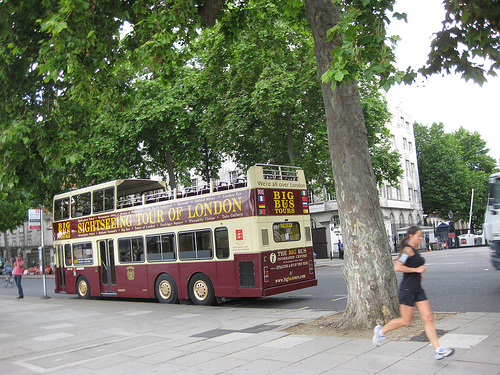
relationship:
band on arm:
[398, 250, 409, 264] [395, 244, 424, 273]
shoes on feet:
[373, 324, 455, 361] [374, 329, 454, 360]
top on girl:
[403, 245, 425, 290] [373, 226, 453, 360]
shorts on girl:
[399, 283, 428, 309] [373, 226, 453, 360]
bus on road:
[53, 166, 317, 306] [0, 267, 499, 309]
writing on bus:
[53, 191, 296, 238] [53, 166, 317, 306]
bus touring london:
[53, 166, 317, 306] [1, 1, 494, 374]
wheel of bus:
[75, 275, 91, 298] [53, 166, 317, 306]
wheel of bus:
[189, 275, 214, 304] [53, 166, 317, 306]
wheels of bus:
[156, 274, 216, 305] [53, 166, 317, 306]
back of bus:
[194, 172, 314, 304] [53, 166, 317, 306]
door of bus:
[97, 240, 117, 296] [53, 166, 317, 306]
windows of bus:
[55, 188, 313, 266] [53, 166, 317, 306]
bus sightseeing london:
[53, 166, 317, 306] [1, 1, 494, 374]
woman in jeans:
[12, 254, 23, 298] [13, 276, 25, 296]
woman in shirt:
[12, 254, 23, 298] [12, 260, 24, 275]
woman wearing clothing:
[373, 226, 453, 360] [397, 245, 428, 305]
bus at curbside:
[53, 166, 317, 306] [6, 292, 500, 316]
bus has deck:
[53, 166, 317, 306] [53, 172, 305, 220]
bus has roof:
[53, 166, 317, 306] [55, 178, 167, 201]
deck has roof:
[53, 172, 305, 220] [55, 178, 167, 201]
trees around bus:
[1, 2, 409, 323] [53, 166, 317, 306]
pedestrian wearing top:
[12, 254, 23, 298] [12, 260, 24, 275]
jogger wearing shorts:
[373, 226, 453, 360] [399, 283, 428, 309]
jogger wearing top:
[373, 226, 453, 360] [403, 245, 425, 290]